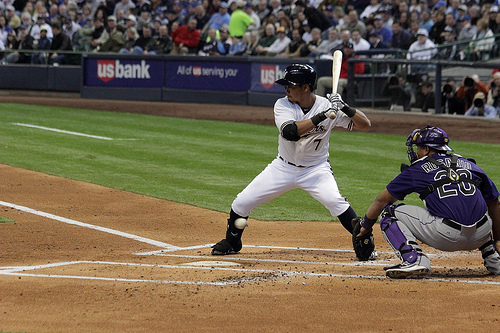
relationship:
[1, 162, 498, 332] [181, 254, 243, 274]
dirt on home plate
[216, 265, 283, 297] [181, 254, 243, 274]
gravel on home plate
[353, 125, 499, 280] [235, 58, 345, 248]
baseball player squatting behind batter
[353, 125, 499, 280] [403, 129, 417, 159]
baseball player wearing mask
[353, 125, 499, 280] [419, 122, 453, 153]
baseball player wearing helmet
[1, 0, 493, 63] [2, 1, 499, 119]
crowd in stands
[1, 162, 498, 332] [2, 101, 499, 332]
dirt on ground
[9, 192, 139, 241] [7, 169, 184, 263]
chalk on baseline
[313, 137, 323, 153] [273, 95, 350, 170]
number on jersey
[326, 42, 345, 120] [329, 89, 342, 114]
bat in hands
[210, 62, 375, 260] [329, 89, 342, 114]
baseball player has hands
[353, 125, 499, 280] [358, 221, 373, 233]
baseball player has hand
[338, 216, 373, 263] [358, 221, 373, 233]
glove on hand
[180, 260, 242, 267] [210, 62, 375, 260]
home plate in baseball player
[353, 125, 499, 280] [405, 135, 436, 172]
baseball player has catcher's face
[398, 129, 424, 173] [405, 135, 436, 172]
mask on catcher's face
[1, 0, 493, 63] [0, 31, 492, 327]
crowd watching game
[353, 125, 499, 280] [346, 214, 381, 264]
baseball player wearing a glove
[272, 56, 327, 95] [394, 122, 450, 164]
helmet on head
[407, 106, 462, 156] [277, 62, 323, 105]
helmet on head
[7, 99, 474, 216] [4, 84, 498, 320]
grass on field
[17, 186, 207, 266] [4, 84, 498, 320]
line on field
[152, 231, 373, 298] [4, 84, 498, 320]
line on field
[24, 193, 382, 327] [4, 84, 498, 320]
line on field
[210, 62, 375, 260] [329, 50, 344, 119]
baseball player holding bat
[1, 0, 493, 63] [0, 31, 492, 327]
crowd looking at game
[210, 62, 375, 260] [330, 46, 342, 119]
baseball player holding bat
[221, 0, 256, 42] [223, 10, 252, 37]
person wearing shirt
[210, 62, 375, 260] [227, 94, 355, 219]
baseball player wearing uniform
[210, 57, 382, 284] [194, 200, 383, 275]
baseball player wearing boots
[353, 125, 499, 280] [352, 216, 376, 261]
baseball player holding glove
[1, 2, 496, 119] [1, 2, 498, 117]
spectators sitting inside bleachers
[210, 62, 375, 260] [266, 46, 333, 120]
baseball player wearing hat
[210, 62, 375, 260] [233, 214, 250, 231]
baseball player hitting ball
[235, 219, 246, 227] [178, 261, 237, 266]
ball crossing over home plate